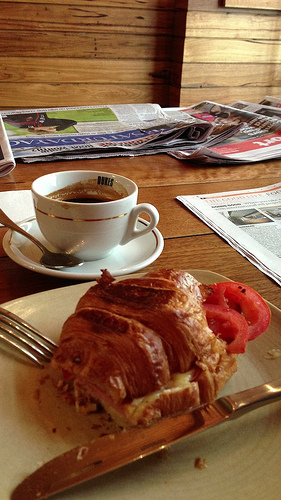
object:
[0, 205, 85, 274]
spoon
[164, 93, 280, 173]
paper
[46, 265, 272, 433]
food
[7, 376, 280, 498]
knife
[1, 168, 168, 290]
cup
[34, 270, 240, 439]
crossaint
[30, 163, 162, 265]
cup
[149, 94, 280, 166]
newpapers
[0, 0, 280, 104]
wall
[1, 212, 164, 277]
saucer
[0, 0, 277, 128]
wall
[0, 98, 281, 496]
table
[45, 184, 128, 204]
coffee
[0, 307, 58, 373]
fork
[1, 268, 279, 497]
plate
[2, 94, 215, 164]
newspaper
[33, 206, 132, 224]
stripe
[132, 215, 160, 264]
stripe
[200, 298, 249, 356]
tomato slice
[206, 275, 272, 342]
tomato slice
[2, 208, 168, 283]
plate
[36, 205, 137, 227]
ring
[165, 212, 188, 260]
table